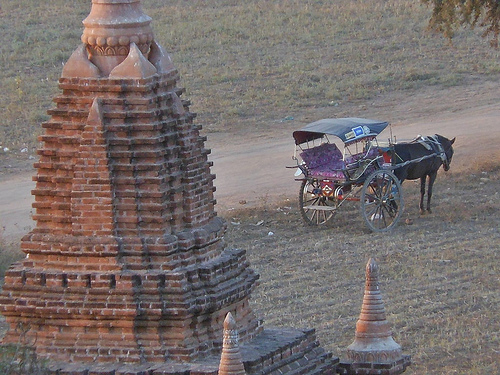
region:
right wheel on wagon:
[362, 173, 386, 230]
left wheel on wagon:
[296, 175, 344, 225]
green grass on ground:
[431, 3, 454, 27]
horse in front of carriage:
[390, 132, 456, 210]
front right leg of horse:
[422, 170, 434, 207]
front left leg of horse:
[417, 176, 424, 214]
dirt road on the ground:
[221, 142, 289, 198]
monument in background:
[8, 0, 398, 373]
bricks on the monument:
[75, 162, 113, 241]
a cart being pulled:
[270, 95, 380, 201]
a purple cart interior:
[301, 137, 366, 197]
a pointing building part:
[331, 265, 410, 363]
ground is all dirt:
[206, 28, 376, 115]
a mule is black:
[357, 105, 473, 208]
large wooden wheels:
[328, 163, 420, 253]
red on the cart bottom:
[306, 175, 361, 214]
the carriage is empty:
[278, 114, 392, 244]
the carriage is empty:
[278, 104, 425, 292]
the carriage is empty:
[293, 111, 398, 246]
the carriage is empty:
[282, 101, 407, 258]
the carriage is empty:
[288, 111, 353, 252]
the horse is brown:
[362, 127, 494, 229]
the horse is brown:
[376, 137, 464, 222]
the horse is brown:
[371, 110, 478, 226]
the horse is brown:
[374, 119, 467, 207]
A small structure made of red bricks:
[0, 7, 270, 369]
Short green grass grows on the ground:
[402, 228, 491, 290]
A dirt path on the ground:
[220, 135, 290, 211]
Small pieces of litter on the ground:
[230, 213, 292, 240]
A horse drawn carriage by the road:
[282, 109, 462, 236]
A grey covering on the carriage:
[290, 112, 392, 151]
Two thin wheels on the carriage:
[295, 168, 405, 236]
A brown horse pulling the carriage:
[371, 133, 469, 211]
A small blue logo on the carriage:
[352, 125, 368, 139]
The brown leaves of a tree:
[420, 3, 498, 40]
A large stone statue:
[6, 8, 397, 374]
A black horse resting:
[381, 130, 461, 214]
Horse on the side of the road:
[204, 78, 498, 222]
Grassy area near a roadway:
[191, 10, 495, 131]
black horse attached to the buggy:
[385, 129, 457, 214]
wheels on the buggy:
[297, 166, 400, 226]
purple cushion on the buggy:
[304, 142, 369, 177]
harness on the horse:
[390, 138, 442, 175]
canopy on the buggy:
[293, 112, 386, 144]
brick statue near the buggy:
[5, 5, 329, 372]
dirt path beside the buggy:
[2, 96, 498, 244]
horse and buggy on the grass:
[303, 110, 459, 229]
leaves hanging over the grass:
[423, 2, 498, 39]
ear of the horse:
[445, 133, 456, 148]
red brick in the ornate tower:
[80, 195, 105, 206]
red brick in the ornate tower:
[93, 202, 114, 210]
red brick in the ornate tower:
[70, 202, 91, 210]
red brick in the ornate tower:
[82, 162, 112, 172]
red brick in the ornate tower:
[80, 205, 98, 218]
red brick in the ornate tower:
[97, 205, 109, 211]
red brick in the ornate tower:
[75, 220, 101, 230]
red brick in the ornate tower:
[100, 222, 112, 229]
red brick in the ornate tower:
[70, 225, 82, 232]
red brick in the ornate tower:
[97, 263, 130, 276]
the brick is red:
[120, 80, 140, 85]